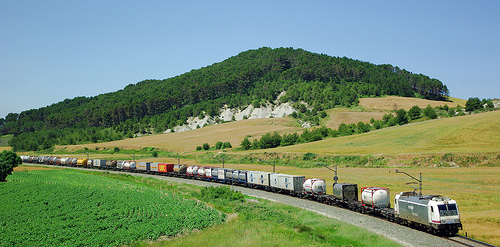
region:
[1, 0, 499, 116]
clear blue sky with no clouds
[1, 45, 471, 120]
hill covered in green trees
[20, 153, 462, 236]
freight train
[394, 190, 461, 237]
engine car of a train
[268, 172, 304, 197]
freight car on a train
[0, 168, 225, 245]
cultivated field full of crop plants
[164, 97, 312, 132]
rocky cliff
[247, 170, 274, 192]
freight car on a train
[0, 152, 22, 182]
tree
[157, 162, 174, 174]
freight car on a train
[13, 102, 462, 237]
a freight train travelling down the tracks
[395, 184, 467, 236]
the locomotive of a freight train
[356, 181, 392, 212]
a tanker car on a freight train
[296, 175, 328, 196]
a tanker car on a freight train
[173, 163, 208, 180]
tankera car on a freight train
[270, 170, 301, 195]
a cargo car on a freight train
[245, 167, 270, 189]
a cargo car on a freight train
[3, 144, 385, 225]
cargo cars on a freight train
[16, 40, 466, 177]
a hillside beside a train track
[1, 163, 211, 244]
the green foliage of a crop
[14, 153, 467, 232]
Train on the tracks.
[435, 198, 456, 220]
Windows on front of train.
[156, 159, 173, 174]
Orange, red freight car.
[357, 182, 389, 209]
White cylinder freight car.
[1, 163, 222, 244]
Crop in the field.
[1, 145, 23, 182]
tree in the bacground.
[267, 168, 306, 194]
silver colored freight car.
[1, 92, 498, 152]
Hills in the background.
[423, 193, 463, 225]
white color on front of train.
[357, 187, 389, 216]
car being pulled by train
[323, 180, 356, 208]
car being pulled by train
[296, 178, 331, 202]
car being pulled by train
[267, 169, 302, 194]
car being pulled by train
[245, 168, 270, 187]
car being pulled by train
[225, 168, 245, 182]
car being pulled by train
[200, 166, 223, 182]
car being pulled by train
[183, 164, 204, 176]
car being pulled by train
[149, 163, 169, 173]
car being pulled by train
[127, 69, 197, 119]
A forest in the background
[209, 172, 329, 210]
A train in the photo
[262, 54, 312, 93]
Trees in the photo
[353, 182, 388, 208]
A tanker on the train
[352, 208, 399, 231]
track ballast on the railway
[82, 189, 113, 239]
Farmlands in the photo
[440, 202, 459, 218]
Windscreen of a train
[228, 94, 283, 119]
Rocks on the hill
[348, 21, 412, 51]
Blue skies in the photo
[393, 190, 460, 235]
Engine pulling a train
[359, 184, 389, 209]
Tank on a train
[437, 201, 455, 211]
Windows on a train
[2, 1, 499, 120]
Blue sky above a train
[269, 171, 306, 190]
Cargo box on a train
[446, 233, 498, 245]
Rails on a train track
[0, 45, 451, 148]
Green trees on a hill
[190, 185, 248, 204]
Green plants beside a train track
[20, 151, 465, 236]
Freight train going through the countryside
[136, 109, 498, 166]
A hill near a train track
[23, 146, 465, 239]
long train traveling on the tracks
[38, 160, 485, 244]
track the train is traveling on